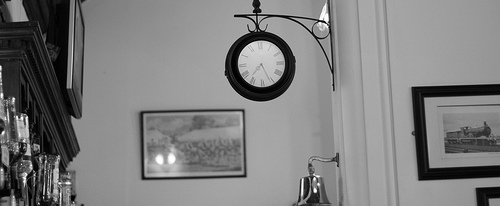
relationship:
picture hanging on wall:
[140, 105, 247, 180] [67, 0, 336, 205]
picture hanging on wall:
[410, 84, 498, 181] [384, 0, 499, 205]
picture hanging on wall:
[473, 186, 499, 204] [384, 0, 499, 205]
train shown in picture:
[444, 120, 490, 145] [410, 84, 498, 181]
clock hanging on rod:
[225, 26, 296, 101] [232, 1, 337, 91]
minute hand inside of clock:
[259, 60, 269, 80] [225, 26, 296, 101]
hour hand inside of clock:
[250, 60, 263, 77] [225, 26, 296, 101]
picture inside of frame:
[410, 84, 498, 181] [409, 84, 499, 178]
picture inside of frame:
[473, 186, 499, 204] [473, 183, 499, 205]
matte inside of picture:
[423, 94, 499, 167] [410, 84, 498, 181]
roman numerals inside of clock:
[238, 40, 284, 86] [225, 26, 296, 101]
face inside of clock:
[236, 39, 286, 86] [225, 26, 296, 101]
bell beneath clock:
[292, 174, 333, 204] [225, 26, 296, 101]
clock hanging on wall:
[225, 26, 296, 101] [67, 0, 336, 205]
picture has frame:
[410, 84, 498, 181] [409, 84, 499, 178]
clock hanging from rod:
[225, 26, 296, 101] [232, 1, 337, 91]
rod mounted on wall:
[232, 1, 337, 91] [67, 0, 336, 205]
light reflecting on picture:
[152, 149, 178, 166] [140, 105, 247, 180]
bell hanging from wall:
[292, 174, 333, 204] [67, 0, 336, 205]